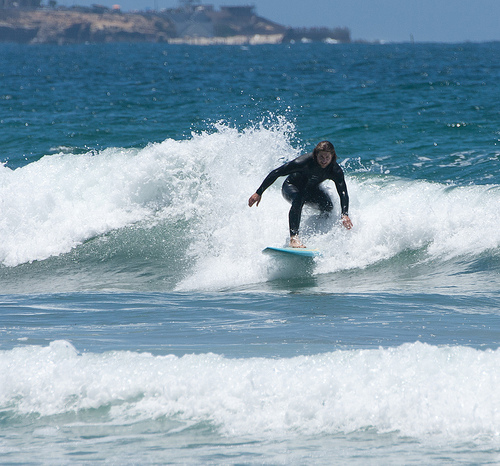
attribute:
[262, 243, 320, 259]
surfboard — blue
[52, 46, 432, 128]
water — bluegreen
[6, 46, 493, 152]
water — bluegreen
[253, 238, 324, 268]
surfboard — blue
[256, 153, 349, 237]
suit — black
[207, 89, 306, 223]
ocean spray — white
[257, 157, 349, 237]
wetsuit — black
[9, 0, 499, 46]
cloudless sky — blue, sunny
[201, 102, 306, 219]
spray — white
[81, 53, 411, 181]
water — bluegreen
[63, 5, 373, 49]
island — hilly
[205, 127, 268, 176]
wave — white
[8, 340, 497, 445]
foam — white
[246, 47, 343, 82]
water — blue, clear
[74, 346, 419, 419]
ocean foam — white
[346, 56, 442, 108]
blue water — calm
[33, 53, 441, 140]
water — bluegreen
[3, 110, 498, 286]
white wave — white 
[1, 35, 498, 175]
blue water — blue 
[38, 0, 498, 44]
sky — blue, clear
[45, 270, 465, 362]
water — blue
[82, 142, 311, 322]
wave — cresting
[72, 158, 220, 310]
waters — calm, blue